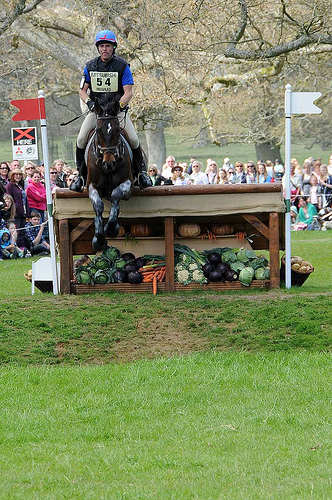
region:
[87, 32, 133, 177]
the man is riding the horse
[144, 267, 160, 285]
the carrots are orange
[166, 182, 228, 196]
the pole is brown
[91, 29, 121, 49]
the helmet is blue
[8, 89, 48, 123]
the flag is red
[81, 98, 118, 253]
the horse is jumping the stand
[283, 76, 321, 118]
the flag is white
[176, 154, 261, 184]
the people are watching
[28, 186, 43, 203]
the shirt is pink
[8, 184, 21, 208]
the coat is purple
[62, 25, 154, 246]
man riding horse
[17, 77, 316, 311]
horse jumping over hurdle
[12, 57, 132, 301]
red flag on end of hurdle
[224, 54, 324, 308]
white flag at end of hurdle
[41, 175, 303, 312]
vegetables at bottom of hurdle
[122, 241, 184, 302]
carrots on bottom of hurdle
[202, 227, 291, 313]
cabbage on bottom of hurdle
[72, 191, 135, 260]
horse has black shoes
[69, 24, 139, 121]
rider wearing number fifty-four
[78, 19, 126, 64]
man wearing blue helmet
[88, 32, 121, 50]
man has blue helmet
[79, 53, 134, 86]
man has black vest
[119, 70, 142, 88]
man has blue shirt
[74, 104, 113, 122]
man has black gloves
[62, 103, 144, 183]
man has tan pants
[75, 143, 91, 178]
man has black boots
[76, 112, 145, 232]
man rides brown horse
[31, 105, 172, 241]
horse jumps brown fence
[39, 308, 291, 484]
green grass under horse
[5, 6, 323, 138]
bare trees behind horse and rider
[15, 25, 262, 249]
a horse competition for jockeys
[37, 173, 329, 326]
this horse is jumping over a vegetable stand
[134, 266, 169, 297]
carrots on the stand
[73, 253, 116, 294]
cabbages on the stand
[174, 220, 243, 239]
pumpkins underneath the stand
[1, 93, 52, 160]
flag on a pole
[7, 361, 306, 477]
green grass in a field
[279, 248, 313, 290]
potatoes in a basket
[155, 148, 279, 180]
a crowd of people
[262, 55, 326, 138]
a white flag on the stand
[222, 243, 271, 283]
Cabbage in the container.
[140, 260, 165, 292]
Carrots in the container.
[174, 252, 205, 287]
Cauliflower heads in container.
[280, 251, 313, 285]
Potatoes in the basket.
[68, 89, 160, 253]
Horse jumping over structure.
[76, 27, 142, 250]
Man riding a horse.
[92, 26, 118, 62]
Blue helmet on the man.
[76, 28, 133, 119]
Black vest on the man.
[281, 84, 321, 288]
White flag pole.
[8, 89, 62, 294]
Red flag on the pole.